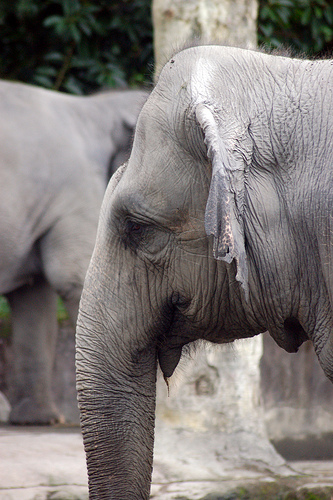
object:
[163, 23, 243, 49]
hair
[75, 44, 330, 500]
elephant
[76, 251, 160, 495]
trunk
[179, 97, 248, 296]
ear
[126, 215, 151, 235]
eye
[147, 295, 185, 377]
mouth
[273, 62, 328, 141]
skin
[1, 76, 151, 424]
elephant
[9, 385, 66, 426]
foot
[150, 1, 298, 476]
tree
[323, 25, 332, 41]
leaves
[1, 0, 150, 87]
bush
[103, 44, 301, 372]
head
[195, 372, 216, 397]
knot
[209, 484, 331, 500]
weeds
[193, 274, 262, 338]
wrinkles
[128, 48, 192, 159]
forehead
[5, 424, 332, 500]
ground